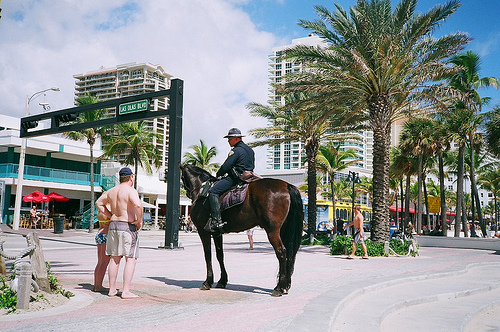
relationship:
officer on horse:
[217, 123, 270, 179] [199, 182, 311, 295]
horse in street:
[199, 182, 311, 295] [313, 243, 488, 332]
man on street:
[104, 169, 150, 296] [313, 243, 488, 332]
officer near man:
[217, 123, 270, 179] [104, 169, 150, 296]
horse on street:
[199, 182, 311, 295] [313, 243, 488, 332]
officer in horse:
[217, 123, 270, 179] [199, 182, 311, 295]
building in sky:
[83, 66, 172, 164] [105, 2, 259, 67]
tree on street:
[303, 16, 479, 231] [313, 243, 488, 332]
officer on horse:
[217, 123, 270, 179] [178, 161, 303, 296]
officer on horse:
[217, 123, 270, 179] [171, 168, 308, 290]